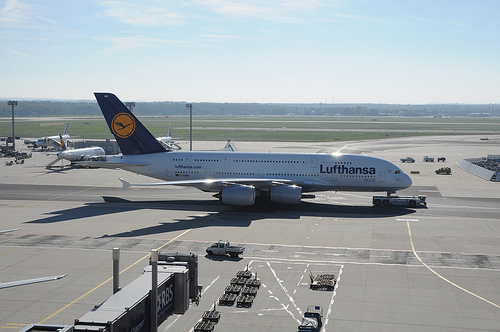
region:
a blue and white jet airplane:
[70, 90, 413, 211]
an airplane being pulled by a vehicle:
[86, 92, 429, 209]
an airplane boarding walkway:
[72, 248, 199, 330]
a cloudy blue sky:
[2, 0, 499, 104]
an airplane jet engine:
[212, 183, 259, 206]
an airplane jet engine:
[265, 182, 302, 205]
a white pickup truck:
[205, 238, 244, 260]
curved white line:
[391, 232, 451, 282]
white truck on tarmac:
[196, 232, 263, 264]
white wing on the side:
[8, 265, 69, 290]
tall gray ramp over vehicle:
[150, 244, 215, 297]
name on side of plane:
[308, 157, 390, 179]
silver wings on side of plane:
[202, 172, 311, 214]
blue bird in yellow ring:
[105, 115, 142, 143]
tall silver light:
[173, 95, 203, 144]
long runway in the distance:
[227, 112, 491, 137]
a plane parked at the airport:
[65, 64, 441, 234]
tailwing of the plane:
[82, 79, 172, 155]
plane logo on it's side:
[320, 159, 385, 179]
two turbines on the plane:
[217, 177, 313, 212]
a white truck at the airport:
[200, 232, 250, 263]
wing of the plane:
[138, 166, 310, 205]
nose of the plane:
[399, 170, 419, 190]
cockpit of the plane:
[385, 159, 405, 185]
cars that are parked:
[392, 143, 455, 180]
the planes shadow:
[32, 192, 214, 254]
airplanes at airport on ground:
[24, 93, 411, 211]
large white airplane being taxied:
[74, 90, 411, 205]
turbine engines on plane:
[214, 173, 303, 211]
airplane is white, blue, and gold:
[71, 90, 413, 210]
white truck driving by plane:
[206, 238, 245, 260]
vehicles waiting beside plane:
[398, 155, 450, 175]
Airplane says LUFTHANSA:
[317, 161, 377, 176]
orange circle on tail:
[111, 112, 135, 137]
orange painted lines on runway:
[1, 183, 499, 330]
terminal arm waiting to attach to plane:
[18, 244, 200, 330]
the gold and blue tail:
[91, 88, 171, 157]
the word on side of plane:
[318, 158, 376, 179]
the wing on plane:
[133, 172, 288, 190]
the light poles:
[2, 95, 199, 153]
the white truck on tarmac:
[204, 236, 246, 258]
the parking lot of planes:
[1, 131, 496, 329]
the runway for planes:
[1, 118, 495, 133]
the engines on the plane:
[213, 178, 303, 209]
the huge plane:
[86, 87, 414, 219]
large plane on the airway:
[66, 89, 417, 212]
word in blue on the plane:
[316, 162, 378, 177]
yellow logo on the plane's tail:
[108, 110, 138, 137]